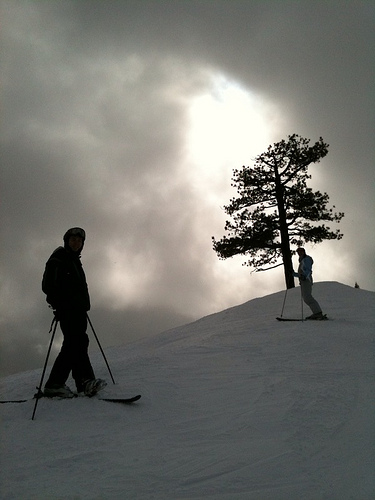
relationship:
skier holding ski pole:
[41, 224, 114, 398] [83, 312, 122, 387]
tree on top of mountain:
[211, 132, 347, 291] [1, 272, 375, 498]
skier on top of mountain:
[41, 224, 114, 398] [1, 272, 375, 498]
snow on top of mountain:
[222, 350, 333, 499] [1, 272, 375, 498]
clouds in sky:
[90, 66, 194, 178] [1, 2, 374, 380]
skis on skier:
[3, 387, 143, 413] [41, 224, 114, 398]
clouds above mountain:
[90, 66, 194, 178] [1, 272, 375, 498]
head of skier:
[63, 226, 84, 253] [41, 224, 114, 398]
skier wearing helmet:
[41, 224, 114, 398] [61, 224, 86, 234]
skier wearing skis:
[41, 224, 114, 398] [3, 387, 143, 413]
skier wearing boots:
[41, 224, 114, 398] [42, 373, 109, 400]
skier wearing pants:
[41, 224, 114, 398] [53, 309, 95, 392]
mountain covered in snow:
[1, 272, 375, 498] [222, 350, 333, 499]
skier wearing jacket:
[41, 224, 114, 398] [41, 246, 90, 330]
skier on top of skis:
[41, 224, 114, 398] [3, 387, 143, 413]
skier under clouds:
[41, 224, 114, 398] [90, 66, 194, 178]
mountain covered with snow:
[1, 272, 375, 498] [222, 350, 333, 499]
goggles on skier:
[62, 226, 87, 236] [41, 224, 114, 398]